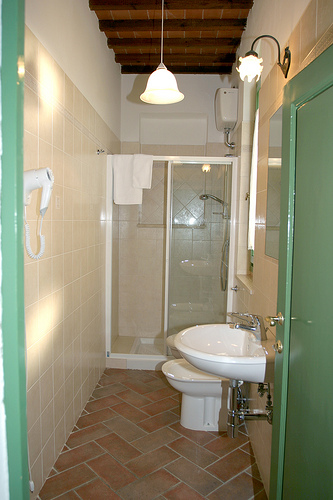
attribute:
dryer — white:
[27, 167, 52, 259]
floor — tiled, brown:
[31, 368, 269, 498]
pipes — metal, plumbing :
[230, 382, 273, 437]